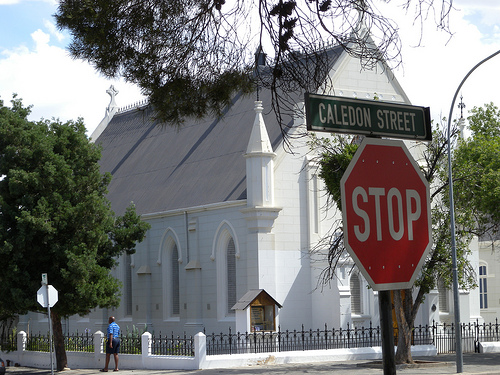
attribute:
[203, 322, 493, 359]
black fence — Small black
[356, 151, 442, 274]
sign — green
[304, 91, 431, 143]
sign — green, white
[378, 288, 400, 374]
pole — black, metal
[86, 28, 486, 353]
building — tall, religious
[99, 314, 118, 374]
man — wearing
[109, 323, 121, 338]
t-shirt — blue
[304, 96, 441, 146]
sign — white, green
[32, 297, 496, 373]
fence — wrought iron ,  block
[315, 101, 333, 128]
white letter — green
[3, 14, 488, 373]
church — white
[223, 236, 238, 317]
window — Large 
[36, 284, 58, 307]
sign — Traffic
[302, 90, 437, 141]
sign — green, white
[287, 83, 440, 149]
sign — white street , Green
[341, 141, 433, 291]
sign — standing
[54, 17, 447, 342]
church — white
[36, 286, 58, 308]
sign — matching stop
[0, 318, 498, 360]
iron fence — black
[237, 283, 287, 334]
board — small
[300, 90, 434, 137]
sign — green